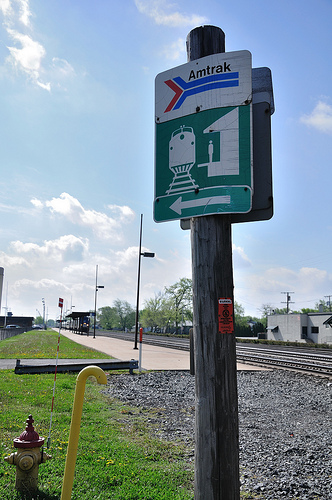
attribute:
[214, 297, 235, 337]
sticker sign — red, orange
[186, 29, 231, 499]
post — wooden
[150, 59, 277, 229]
train sign — green, white, metal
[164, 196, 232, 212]
arrow — white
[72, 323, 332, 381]
train track — parallel, long, parrallel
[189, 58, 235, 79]
amtrack — black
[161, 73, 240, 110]
amtrack logo — blue, red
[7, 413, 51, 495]
fire hydrant — small, yellow,  red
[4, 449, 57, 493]
bottom — yellow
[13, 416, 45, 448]
top — red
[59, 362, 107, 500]
pipe — yellow, curved, crooked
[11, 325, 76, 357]
grass — green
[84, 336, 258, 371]
platform — paved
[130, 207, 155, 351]
lamp post — black, tall, off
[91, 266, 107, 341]
lamp post — black, tall, off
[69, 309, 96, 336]
shelter — small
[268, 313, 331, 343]
building — white, one floor, blocky, concrete, short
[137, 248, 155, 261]
head — square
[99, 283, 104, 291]
head — square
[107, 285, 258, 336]
trees — green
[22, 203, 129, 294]
clouds — white, fluffy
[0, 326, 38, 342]
fence — metal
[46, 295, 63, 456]
pole — red, white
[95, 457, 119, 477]
dandelions — yellow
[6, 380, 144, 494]
field — small, grassy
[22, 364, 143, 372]
rail guard — metal